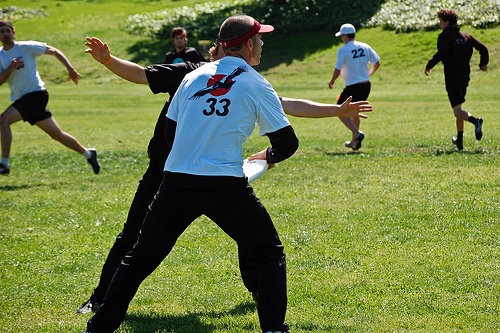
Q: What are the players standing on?
A: Grass.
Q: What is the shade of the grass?
A: Green.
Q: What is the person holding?
A: A frisbee.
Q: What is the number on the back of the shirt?
A: 22.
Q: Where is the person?
A: Field.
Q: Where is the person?
A: Field.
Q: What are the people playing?
A: Frisbee.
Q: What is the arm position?
A: Open.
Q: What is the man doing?
A: Running.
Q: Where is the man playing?
A: Park.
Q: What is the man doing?
A: Blocking.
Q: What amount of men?
A: Six.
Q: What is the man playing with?
A: Frisbee.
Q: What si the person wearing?
A: Cap.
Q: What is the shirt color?
A: White.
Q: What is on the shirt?
A: Logo.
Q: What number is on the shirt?
A: 33.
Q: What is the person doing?
A: Running.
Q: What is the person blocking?
A: Frisbee.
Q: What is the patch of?
A: Grass.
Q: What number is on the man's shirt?
A: 33.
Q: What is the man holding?
A: A frisbee.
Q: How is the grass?
A: Green.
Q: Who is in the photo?
A: People.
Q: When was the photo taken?
A: Daytime.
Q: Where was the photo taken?
A: At a park.